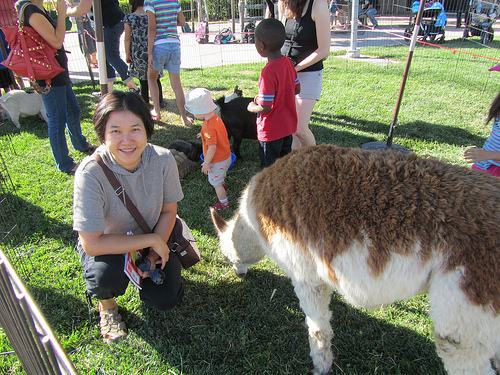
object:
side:
[0, 259, 86, 374]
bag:
[90, 151, 201, 269]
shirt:
[200, 113, 231, 164]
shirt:
[256, 55, 301, 142]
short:
[75, 253, 133, 303]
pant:
[150, 271, 186, 299]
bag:
[0, 2, 66, 96]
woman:
[13, 0, 101, 175]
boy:
[183, 87, 233, 211]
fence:
[194, 0, 259, 77]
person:
[72, 89, 185, 345]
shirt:
[73, 141, 185, 235]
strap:
[90, 152, 153, 233]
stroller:
[216, 87, 261, 146]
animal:
[207, 141, 499, 374]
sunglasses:
[133, 255, 165, 285]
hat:
[182, 87, 217, 114]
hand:
[135, 250, 158, 279]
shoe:
[97, 301, 129, 347]